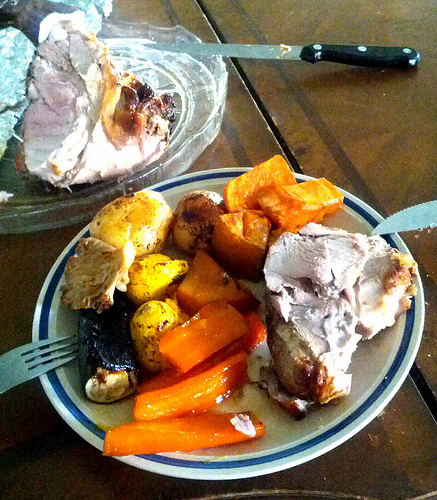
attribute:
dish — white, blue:
[39, 152, 420, 457]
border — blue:
[391, 349, 409, 372]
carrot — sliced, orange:
[156, 301, 254, 369]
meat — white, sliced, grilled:
[269, 223, 411, 409]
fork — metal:
[0, 332, 86, 380]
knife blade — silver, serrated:
[146, 33, 304, 67]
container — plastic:
[0, 8, 229, 213]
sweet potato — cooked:
[258, 178, 353, 230]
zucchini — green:
[72, 305, 138, 400]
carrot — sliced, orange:
[142, 364, 252, 416]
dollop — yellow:
[132, 255, 191, 304]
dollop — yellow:
[127, 299, 193, 340]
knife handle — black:
[304, 36, 420, 73]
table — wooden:
[6, 3, 435, 488]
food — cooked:
[69, 251, 121, 297]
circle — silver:
[313, 41, 323, 54]